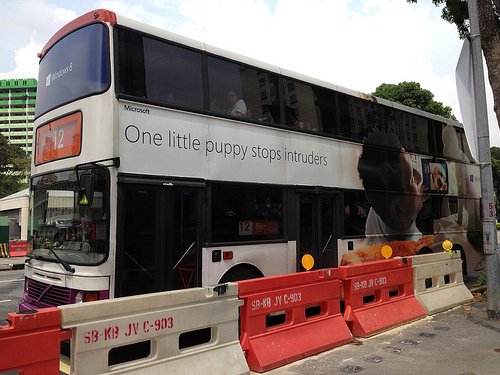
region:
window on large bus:
[31, 17, 111, 112]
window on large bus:
[108, 20, 209, 111]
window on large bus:
[202, 52, 266, 129]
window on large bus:
[258, 70, 315, 128]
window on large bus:
[316, 85, 367, 140]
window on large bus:
[386, 110, 433, 155]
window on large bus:
[116, 171, 209, 288]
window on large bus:
[202, 169, 294, 251]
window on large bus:
[304, 184, 343, 269]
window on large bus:
[345, 190, 395, 242]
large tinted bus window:
[113, 21, 201, 104]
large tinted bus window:
[206, 51, 278, 121]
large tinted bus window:
[271, 75, 337, 137]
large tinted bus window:
[340, 94, 395, 142]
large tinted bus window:
[399, 109, 431, 153]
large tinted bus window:
[213, 184, 286, 236]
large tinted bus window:
[341, 195, 396, 236]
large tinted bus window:
[397, 198, 437, 232]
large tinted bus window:
[437, 120, 461, 158]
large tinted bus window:
[34, 25, 113, 112]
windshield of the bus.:
[60, 203, 82, 213]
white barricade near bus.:
[178, 305, 203, 322]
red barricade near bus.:
[277, 324, 324, 346]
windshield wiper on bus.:
[39, 246, 84, 283]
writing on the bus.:
[127, 126, 184, 145]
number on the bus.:
[45, 128, 70, 149]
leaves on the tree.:
[392, 86, 419, 94]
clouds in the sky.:
[290, 22, 325, 38]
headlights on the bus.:
[71, 293, 99, 302]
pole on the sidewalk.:
[486, 70, 492, 252]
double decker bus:
[28, 8, 496, 313]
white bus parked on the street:
[33, 4, 499, 322]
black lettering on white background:
[125, 117, 329, 170]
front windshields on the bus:
[37, 37, 124, 254]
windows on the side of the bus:
[120, 46, 472, 279]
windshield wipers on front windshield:
[19, 235, 74, 277]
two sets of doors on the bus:
[116, 182, 346, 322]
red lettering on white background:
[77, 305, 176, 357]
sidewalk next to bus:
[299, 303, 499, 368]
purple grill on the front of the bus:
[20, 279, 67, 311]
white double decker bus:
[30, 83, 494, 313]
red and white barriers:
[37, 237, 461, 372]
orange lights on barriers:
[291, 228, 456, 278]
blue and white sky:
[117, 1, 404, 75]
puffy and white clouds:
[182, 17, 379, 67]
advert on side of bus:
[118, 104, 420, 258]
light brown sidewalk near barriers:
[295, 304, 485, 372]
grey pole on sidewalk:
[461, 7, 498, 317]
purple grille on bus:
[2, 273, 94, 317]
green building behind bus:
[1, 48, 38, 192]